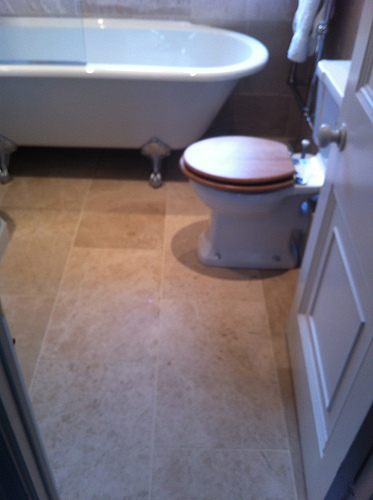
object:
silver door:
[291, 0, 372, 499]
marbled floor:
[2, 157, 305, 497]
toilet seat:
[175, 133, 307, 265]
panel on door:
[284, 6, 372, 499]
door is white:
[288, 0, 371, 499]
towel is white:
[284, 0, 334, 62]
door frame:
[286, 0, 372, 496]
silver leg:
[141, 153, 165, 191]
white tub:
[1, 12, 267, 187]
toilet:
[175, 129, 307, 274]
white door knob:
[311, 119, 350, 151]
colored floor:
[1, 163, 311, 494]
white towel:
[286, 1, 337, 62]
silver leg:
[0, 143, 15, 185]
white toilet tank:
[307, 61, 354, 158]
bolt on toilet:
[214, 250, 221, 262]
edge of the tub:
[203, 22, 273, 103]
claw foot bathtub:
[1, 16, 270, 188]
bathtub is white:
[0, 15, 269, 187]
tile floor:
[1, 138, 306, 498]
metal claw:
[142, 139, 167, 158]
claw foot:
[136, 133, 178, 186]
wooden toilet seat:
[167, 134, 300, 197]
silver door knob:
[306, 117, 351, 156]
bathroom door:
[284, 1, 371, 499]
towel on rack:
[287, 0, 337, 78]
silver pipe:
[285, 55, 319, 133]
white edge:
[186, 25, 274, 91]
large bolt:
[270, 249, 289, 264]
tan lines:
[31, 172, 308, 499]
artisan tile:
[71, 193, 167, 251]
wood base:
[167, 130, 297, 193]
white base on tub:
[5, 119, 197, 155]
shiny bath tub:
[1, 16, 269, 181]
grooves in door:
[277, 0, 371, 499]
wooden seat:
[167, 126, 304, 277]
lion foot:
[137, 137, 167, 191]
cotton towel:
[283, 0, 329, 66]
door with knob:
[286, 1, 371, 499]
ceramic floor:
[0, 173, 301, 498]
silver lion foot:
[136, 138, 173, 187]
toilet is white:
[176, 135, 319, 277]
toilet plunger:
[300, 133, 316, 156]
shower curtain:
[2, 0, 251, 74]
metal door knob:
[312, 119, 353, 152]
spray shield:
[1, 3, 86, 73]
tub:
[0, 15, 270, 185]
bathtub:
[1, 17, 271, 148]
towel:
[286, 0, 335, 62]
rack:
[284, 1, 338, 126]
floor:
[3, 132, 308, 498]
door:
[286, 3, 371, 497]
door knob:
[313, 120, 348, 153]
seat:
[174, 129, 313, 197]